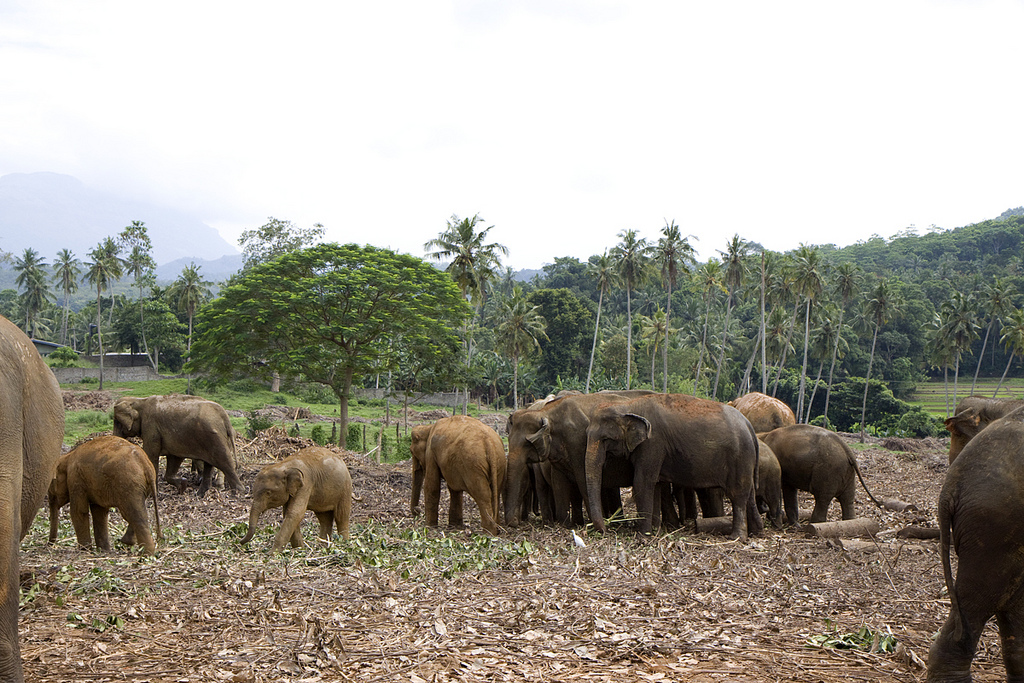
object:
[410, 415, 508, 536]
elephant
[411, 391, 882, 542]
huddle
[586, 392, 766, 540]
elephant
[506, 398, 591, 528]
elephant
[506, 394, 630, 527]
elephant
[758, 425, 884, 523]
elephant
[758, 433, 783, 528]
elephant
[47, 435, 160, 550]
elephant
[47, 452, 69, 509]
head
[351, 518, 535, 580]
grass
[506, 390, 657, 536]
elephant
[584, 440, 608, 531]
trunk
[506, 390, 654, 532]
elephant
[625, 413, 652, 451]
ear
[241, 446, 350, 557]
elephant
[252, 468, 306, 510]
head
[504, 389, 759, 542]
elephant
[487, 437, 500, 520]
tail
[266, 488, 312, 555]
legs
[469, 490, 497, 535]
legs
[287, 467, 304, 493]
ear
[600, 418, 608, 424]
eye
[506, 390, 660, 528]
elephant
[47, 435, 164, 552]
elephant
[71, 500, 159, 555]
feet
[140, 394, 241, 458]
body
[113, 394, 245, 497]
elephant